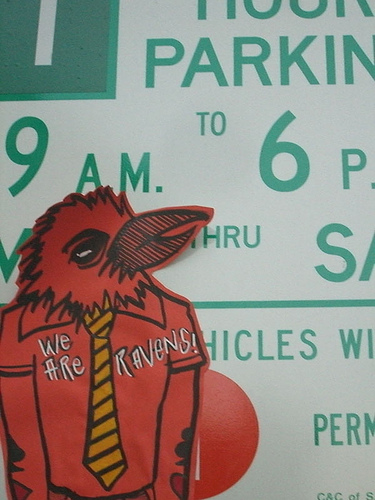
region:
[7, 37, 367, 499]
View of sign, likely taken in daytime, but unverifiable.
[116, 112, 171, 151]
White surface of sign.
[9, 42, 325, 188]
Green text, showing numbers and letters.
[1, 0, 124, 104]
Box with dark and light green.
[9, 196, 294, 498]
Cartoon of bird on sign.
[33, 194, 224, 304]
Red, raven head with beak, pointing right.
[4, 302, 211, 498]
Tatooed arms and shirt, on raven.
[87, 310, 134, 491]
Yellow tie, with black stripes, on raven.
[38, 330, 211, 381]
"We Are Ravens," written across cartoon.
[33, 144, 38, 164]
Green numbers on a white sign.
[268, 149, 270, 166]
Green numbers on a white sign.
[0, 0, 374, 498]
the green and white parking sign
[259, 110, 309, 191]
the number 6 on the sign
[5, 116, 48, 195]
the number 9 on the sign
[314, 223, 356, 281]
the letter "S" on the sign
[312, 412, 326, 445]
the letter "P" on the sign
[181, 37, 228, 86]
the letter "A" on the sign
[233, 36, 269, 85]
the letter "R" on the sign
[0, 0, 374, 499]
the green letters on the sign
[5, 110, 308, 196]
the green numbers on the sign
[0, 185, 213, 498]
the red bird on the sign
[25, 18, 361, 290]
green and white sign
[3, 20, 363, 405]
green letters on sign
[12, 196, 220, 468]
small sticker is red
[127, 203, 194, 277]
black beak on bird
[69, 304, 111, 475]
orange and black tie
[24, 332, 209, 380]
black and white slogan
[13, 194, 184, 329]
bird has thick hair on head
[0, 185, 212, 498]
red wooden bird mascot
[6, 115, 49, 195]
green number nine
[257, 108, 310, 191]
green number six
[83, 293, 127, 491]
tie on bird mascot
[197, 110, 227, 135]
green letters spelling "to"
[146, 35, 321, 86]
green letters spelling "park"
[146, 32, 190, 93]
a letter on the sign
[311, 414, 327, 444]
a letter on the sign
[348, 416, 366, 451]
a letter on the sign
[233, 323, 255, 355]
a letter on the sign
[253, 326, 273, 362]
a letter on the sign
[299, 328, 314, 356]
a letter on the sign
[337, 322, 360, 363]
a letter on the sign